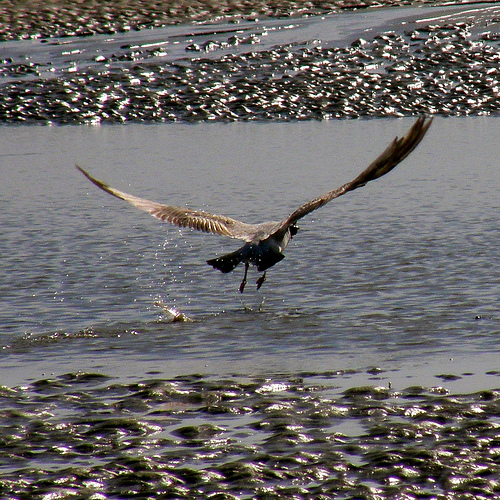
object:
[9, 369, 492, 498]
seaweed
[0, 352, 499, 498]
shore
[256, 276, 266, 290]
foot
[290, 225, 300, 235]
head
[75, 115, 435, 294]
bird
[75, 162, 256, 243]
outstretched wing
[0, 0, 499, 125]
wet rocks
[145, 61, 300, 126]
rocks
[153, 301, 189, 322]
fish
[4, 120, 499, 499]
water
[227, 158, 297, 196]
ripples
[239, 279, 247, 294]
feet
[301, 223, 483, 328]
ripples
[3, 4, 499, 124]
shore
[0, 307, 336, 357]
ripples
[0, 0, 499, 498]
ground